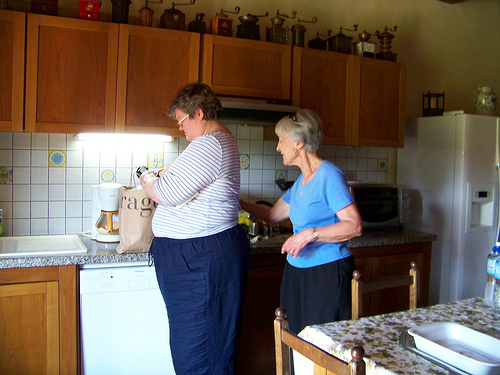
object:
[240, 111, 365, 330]
lady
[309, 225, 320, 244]
watch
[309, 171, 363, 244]
arm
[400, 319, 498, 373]
dish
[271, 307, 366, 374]
chair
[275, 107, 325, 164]
woman's head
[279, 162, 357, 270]
shirt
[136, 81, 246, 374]
woman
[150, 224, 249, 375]
pants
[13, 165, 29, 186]
tile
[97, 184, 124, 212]
candle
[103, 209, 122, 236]
stand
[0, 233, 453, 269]
countertop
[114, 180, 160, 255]
bag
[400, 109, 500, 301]
refrigerator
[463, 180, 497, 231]
icemaker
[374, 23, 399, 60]
coffee grinders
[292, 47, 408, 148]
cabinets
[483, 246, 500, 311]
water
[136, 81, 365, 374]
friends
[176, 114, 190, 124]
eye glasses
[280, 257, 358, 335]
pants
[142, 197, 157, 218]
letters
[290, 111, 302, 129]
sunglasses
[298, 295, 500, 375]
table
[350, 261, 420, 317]
chair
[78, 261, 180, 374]
dishwasher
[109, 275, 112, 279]
dot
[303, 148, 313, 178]
vein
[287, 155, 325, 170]
neck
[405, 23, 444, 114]
shadow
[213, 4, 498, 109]
wall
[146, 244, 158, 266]
string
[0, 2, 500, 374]
kitchen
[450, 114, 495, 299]
door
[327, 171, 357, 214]
sleeves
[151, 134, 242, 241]
striped shirt